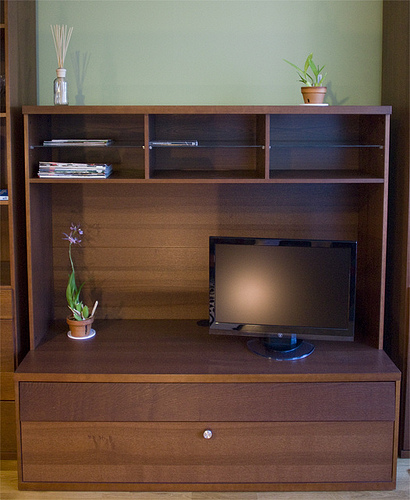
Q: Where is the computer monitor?
A: On the shelf.